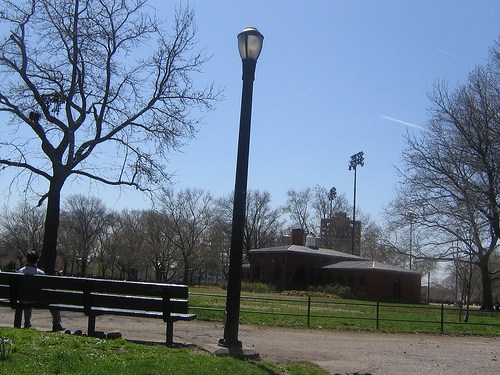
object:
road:
[0, 305, 497, 373]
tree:
[281, 186, 316, 236]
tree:
[0, 200, 47, 258]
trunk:
[38, 178, 65, 274]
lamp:
[236, 27, 265, 61]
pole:
[350, 166, 357, 255]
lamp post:
[216, 28, 264, 346]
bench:
[1, 271, 194, 343]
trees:
[215, 188, 284, 264]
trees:
[147, 187, 221, 286]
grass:
[0, 329, 322, 375]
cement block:
[202, 344, 260, 360]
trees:
[312, 184, 351, 249]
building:
[318, 212, 361, 256]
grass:
[189, 285, 499, 337]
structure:
[319, 260, 423, 304]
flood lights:
[348, 149, 365, 171]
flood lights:
[327, 187, 338, 201]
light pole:
[215, 61, 256, 348]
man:
[16, 249, 68, 331]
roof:
[249, 244, 370, 260]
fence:
[189, 290, 499, 333]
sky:
[0, 0, 499, 246]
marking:
[380, 115, 432, 132]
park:
[0, 217, 497, 372]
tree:
[0, 0, 226, 275]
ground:
[0, 306, 499, 372]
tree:
[373, 45, 498, 314]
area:
[0, 324, 325, 374]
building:
[248, 228, 373, 293]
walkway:
[0, 301, 497, 372]